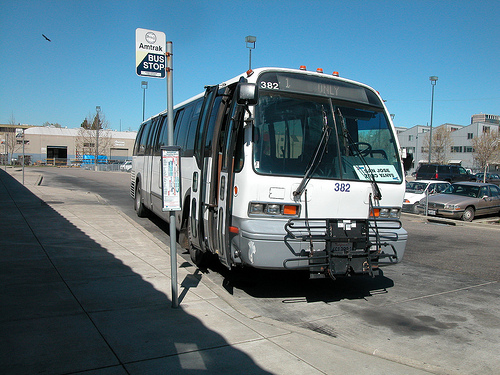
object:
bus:
[128, 68, 416, 285]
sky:
[60, 4, 89, 28]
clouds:
[406, 110, 424, 119]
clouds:
[113, 116, 129, 126]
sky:
[324, 12, 376, 44]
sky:
[437, 13, 459, 36]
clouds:
[458, 93, 471, 107]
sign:
[127, 20, 170, 90]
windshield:
[258, 95, 401, 185]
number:
[339, 180, 355, 196]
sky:
[344, 8, 379, 15]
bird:
[36, 32, 55, 42]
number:
[325, 177, 357, 193]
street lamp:
[418, 66, 450, 187]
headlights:
[245, 204, 296, 222]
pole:
[150, 42, 190, 307]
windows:
[447, 137, 472, 160]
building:
[447, 113, 479, 161]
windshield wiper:
[276, 124, 345, 202]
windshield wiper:
[332, 119, 388, 197]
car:
[388, 175, 449, 218]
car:
[416, 170, 490, 224]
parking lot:
[416, 218, 499, 263]